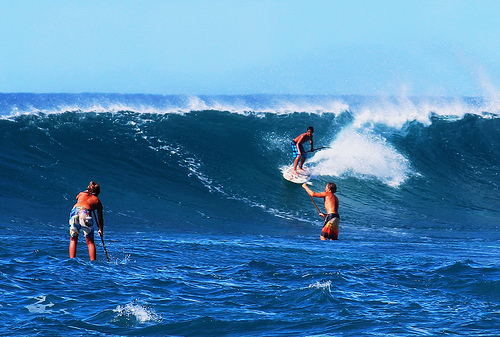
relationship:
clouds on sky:
[0, 0, 499, 94] [2, 3, 499, 94]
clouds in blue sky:
[0, 0, 499, 94] [0, 1, 498, 98]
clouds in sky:
[0, 0, 499, 94] [101, 24, 259, 92]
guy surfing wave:
[284, 121, 319, 176] [4, 89, 499, 186]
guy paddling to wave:
[68, 181, 106, 262] [0, 109, 498, 227]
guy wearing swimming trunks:
[62, 175, 112, 261] [67, 207, 94, 236]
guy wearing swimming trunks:
[290, 126, 315, 175] [288, 140, 304, 163]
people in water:
[23, 94, 428, 279] [155, 250, 472, 317]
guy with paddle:
[68, 181, 106, 262] [92, 218, 113, 256]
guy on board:
[68, 181, 106, 262] [50, 259, 98, 263]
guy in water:
[301, 183, 339, 240] [2, 92, 498, 334]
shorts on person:
[300, 211, 362, 238] [315, 182, 342, 254]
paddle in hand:
[302, 184, 324, 216] [303, 185, 313, 198]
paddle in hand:
[302, 184, 324, 216] [313, 207, 323, 217]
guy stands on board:
[290, 126, 315, 175] [280, 164, 313, 191]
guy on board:
[290, 126, 315, 175] [283, 156, 315, 188]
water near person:
[160, 198, 262, 275] [64, 179, 105, 264]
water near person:
[160, 198, 262, 275] [314, 185, 338, 238]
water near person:
[160, 198, 262, 275] [288, 128, 315, 188]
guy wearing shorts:
[299, 182, 339, 237] [321, 213, 341, 241]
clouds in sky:
[0, 0, 499, 94] [2, 3, 499, 94]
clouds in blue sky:
[267, 16, 348, 92] [0, 1, 498, 98]